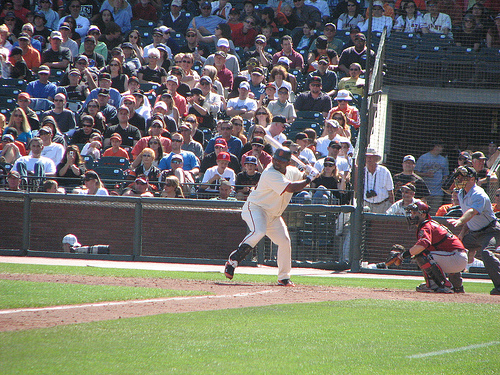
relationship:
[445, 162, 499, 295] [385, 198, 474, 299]
umpire standing behind catcher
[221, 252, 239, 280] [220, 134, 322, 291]
foot of batter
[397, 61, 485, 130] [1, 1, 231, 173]
netting in front of fans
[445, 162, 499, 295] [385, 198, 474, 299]
umpire behind catcher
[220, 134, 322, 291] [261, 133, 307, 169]
batter has a bat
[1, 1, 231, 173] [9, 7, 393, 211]
fans are in stand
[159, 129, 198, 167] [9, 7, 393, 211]
fan in stand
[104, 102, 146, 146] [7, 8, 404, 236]
fan in stand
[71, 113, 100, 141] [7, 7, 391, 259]
fan in stand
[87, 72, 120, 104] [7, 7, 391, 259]
fan in stand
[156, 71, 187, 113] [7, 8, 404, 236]
fan in stand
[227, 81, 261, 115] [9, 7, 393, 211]
fan in stand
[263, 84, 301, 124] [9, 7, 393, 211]
fan in stand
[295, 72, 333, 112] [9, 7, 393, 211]
fan in stand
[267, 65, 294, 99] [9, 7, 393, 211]
fan in stand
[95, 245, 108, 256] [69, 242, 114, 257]
lens on camera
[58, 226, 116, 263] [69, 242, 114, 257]
photographer has camera